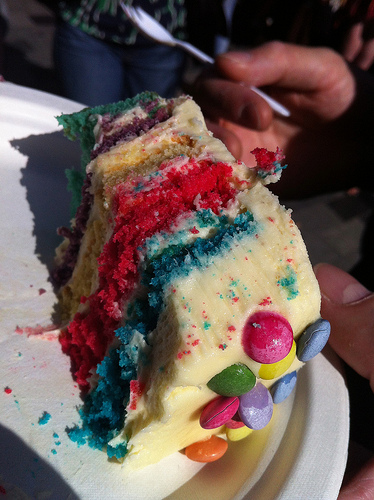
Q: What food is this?
A: Cake.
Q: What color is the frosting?
A: White.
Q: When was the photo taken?
A: Daytime.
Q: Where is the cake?
A: On a plate.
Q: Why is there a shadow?
A: It is sunny.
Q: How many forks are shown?
A: One.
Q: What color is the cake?
A: Red, White, and Blue.